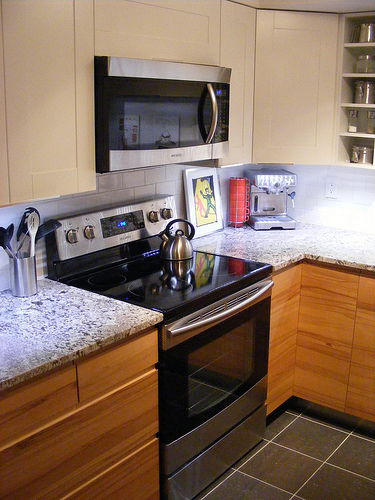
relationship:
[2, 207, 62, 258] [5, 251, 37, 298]
utensils in a pot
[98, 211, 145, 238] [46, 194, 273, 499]
display on stove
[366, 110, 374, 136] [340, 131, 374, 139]
shaker on self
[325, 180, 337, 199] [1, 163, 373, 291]
outlet on top of wall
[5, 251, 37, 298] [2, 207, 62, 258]
pot holding utensils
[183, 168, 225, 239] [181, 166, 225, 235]
picture in side of frame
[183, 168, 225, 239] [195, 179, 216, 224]
picture with man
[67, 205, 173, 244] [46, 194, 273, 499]
knobs on stove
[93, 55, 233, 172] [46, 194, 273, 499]
microwave above stove